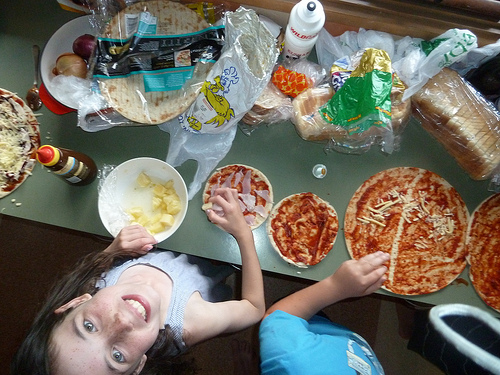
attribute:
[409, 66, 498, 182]
bread`s slices — white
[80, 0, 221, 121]
pita bread — round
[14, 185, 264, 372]
girl — sleeveless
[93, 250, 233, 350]
top — blue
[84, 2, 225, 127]
tortillas — big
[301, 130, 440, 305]
pizza — cheese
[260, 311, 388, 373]
top — blue